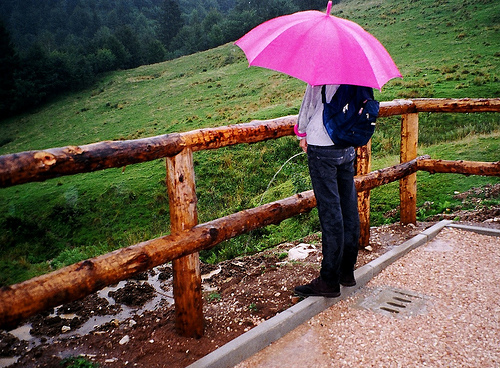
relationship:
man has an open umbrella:
[291, 40, 379, 297] [234, 0, 408, 92]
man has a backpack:
[291, 40, 379, 297] [322, 84, 377, 146]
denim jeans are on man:
[305, 145, 357, 278] [290, 75, 379, 306]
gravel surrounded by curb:
[238, 229, 499, 366] [193, 222, 496, 367]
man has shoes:
[266, 40, 406, 337] [281, 250, 388, 315]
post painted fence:
[160, 134, 207, 337] [0, 96, 500, 340]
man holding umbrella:
[291, 40, 379, 297] [237, 2, 402, 139]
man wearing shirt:
[291, 40, 379, 297] [293, 81, 357, 163]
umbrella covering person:
[236, 4, 433, 99] [250, 32, 402, 303]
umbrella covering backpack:
[236, 0, 401, 93] [321, 83, 379, 155]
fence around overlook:
[163, 117, 290, 249] [6, 96, 484, 352]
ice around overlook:
[84, 312, 127, 336] [1, 84, 495, 365]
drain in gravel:
[352, 287, 427, 319] [232, 214, 499, 366]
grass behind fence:
[0, 24, 497, 222] [0, 90, 498, 335]